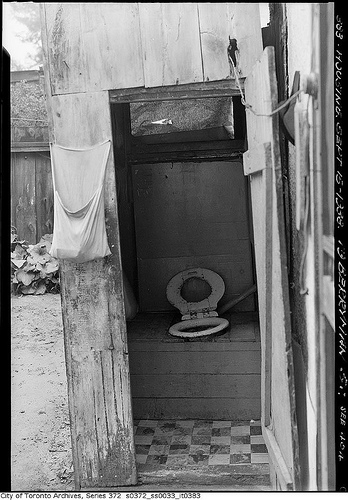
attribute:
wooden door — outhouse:
[207, 63, 316, 482]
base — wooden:
[142, 262, 277, 409]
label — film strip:
[123, 94, 268, 156]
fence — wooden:
[0, 143, 55, 278]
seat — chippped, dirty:
[166, 269, 227, 340]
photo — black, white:
[6, 6, 327, 488]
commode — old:
[166, 266, 230, 338]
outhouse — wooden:
[39, 1, 300, 488]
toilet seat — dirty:
[164, 267, 229, 341]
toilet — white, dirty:
[147, 258, 252, 363]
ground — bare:
[208, 62, 272, 104]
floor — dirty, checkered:
[133, 416, 307, 486]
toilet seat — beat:
[127, 252, 243, 354]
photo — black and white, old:
[0, 1, 348, 499]